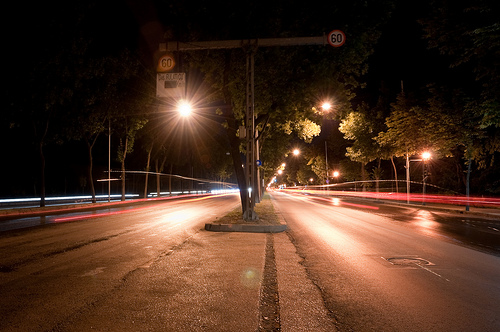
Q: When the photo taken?
A: Nighttime.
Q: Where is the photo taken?
A: At a road.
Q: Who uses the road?
A: Drivers.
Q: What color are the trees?
A: Green.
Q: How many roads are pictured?
A: Two.